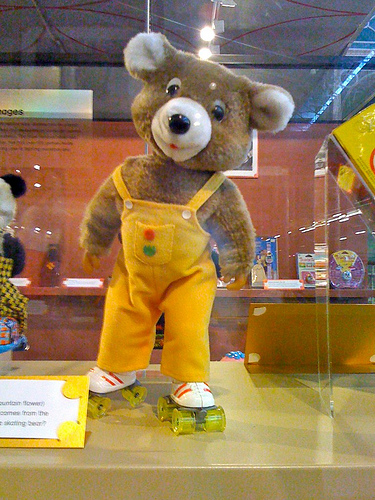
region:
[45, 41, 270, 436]
stuffed bear wearing roller skates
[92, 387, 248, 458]
roller skate wheels are yellow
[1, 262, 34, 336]
bear wearing checked outfit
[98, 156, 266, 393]
stuffed bear wearing yellow coveralls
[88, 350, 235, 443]
roller skates have two red stripes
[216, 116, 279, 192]
picture hanging on the wall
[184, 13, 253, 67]
ceiling light reflection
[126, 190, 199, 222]
white buttons on the coverall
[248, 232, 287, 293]
picture of Beauty and the Beast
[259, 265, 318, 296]
sign on the counter top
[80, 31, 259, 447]
bear is large and brown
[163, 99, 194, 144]
bear has black nose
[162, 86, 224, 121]
bear has large black eyes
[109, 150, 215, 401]
bear wears yellow overalls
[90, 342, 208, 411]
white shoes with orange stripe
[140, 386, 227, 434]
yellow rollerskates on shoes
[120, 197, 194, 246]
white buttons on overalls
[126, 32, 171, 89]
large white ears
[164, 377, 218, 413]
orange stripes on shoes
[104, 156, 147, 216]
yellow straps on overalls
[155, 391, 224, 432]
The yellow wheels on the bear's left skate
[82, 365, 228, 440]
The roller skates on the bear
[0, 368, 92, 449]
The paper placard in front of the bear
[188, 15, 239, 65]
The lights that are shown on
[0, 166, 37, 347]
The panda bear on the left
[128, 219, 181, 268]
The pocket on the bear's overalls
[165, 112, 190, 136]
The nose of the bear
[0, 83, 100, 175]
The clear sign with black writing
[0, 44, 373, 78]
The black bar behind the bear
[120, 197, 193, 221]
The buttons on the overalls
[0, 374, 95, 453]
a sign for the display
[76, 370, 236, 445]
skates with yellow wheels on the bear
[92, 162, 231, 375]
yellow overalls worn by the stuffed animal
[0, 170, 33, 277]
a stuffed panda bear in a case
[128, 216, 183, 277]
a pocket with orange and green buttons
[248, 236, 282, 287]
a pink digital watch in the case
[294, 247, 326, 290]
a small digital toy in the case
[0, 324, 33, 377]
a blue seat for the stuff animal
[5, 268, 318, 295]
orange signs for the toy display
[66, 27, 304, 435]
a brown stuffed bear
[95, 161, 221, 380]
the bears yellow overalls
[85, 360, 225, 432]
the skates on the bear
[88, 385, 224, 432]
the yellow wheels on the skates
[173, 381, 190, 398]
the stripes on the roller skates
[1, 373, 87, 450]
the sign in front of the bear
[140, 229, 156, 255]
the orange and green design on the overalls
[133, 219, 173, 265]
the pocket on the overalls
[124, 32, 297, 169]
the head of the stuffed bear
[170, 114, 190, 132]
the nose on the stuffed bear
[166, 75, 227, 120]
the eyes on the stuffed bear